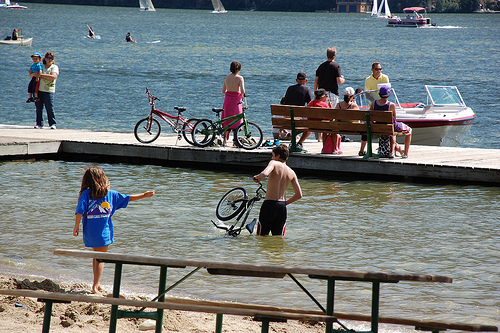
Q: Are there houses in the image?
A: No, there are no houses.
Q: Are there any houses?
A: No, there are no houses.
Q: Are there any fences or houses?
A: No, there are no houses or fences.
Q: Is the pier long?
A: Yes, the pier is long.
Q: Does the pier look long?
A: Yes, the pier is long.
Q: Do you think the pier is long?
A: Yes, the pier is long.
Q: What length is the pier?
A: The pier is long.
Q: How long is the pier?
A: The pier is long.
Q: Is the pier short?
A: No, the pier is long.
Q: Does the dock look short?
A: No, the dock is long.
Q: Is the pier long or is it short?
A: The pier is long.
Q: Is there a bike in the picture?
A: Yes, there is a bike.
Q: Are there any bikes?
A: Yes, there is a bike.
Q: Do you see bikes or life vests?
A: Yes, there is a bike.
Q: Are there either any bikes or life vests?
A: Yes, there is a bike.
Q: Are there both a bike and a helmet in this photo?
A: No, there is a bike but no helmets.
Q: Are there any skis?
A: No, there are no skis.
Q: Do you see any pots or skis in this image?
A: No, there are no skis or pots.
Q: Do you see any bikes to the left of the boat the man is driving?
A: Yes, there is a bike to the left of the boat.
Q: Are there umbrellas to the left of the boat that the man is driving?
A: No, there is a bike to the left of the boat.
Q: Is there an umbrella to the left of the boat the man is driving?
A: No, there is a bike to the left of the boat.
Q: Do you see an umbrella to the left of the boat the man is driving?
A: No, there is a bike to the left of the boat.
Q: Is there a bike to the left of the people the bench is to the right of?
A: Yes, there is a bike to the left of the people.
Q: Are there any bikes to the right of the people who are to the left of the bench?
A: No, the bike is to the left of the people.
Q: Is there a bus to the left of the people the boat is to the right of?
A: No, there is a bike to the left of the people.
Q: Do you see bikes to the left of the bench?
A: Yes, there is a bike to the left of the bench.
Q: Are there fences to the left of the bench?
A: No, there is a bike to the left of the bench.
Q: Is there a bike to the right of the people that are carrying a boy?
A: Yes, there is a bike to the right of the people.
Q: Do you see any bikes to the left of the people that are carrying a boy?
A: No, the bike is to the right of the people.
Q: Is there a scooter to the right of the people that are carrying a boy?
A: No, there is a bike to the right of the people.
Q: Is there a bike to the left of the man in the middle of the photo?
A: Yes, there is a bike to the left of the man.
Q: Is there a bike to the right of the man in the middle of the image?
A: No, the bike is to the left of the man.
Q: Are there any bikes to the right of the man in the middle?
A: No, the bike is to the left of the man.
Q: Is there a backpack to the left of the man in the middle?
A: No, there is a bike to the left of the man.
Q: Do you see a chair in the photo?
A: No, there are no chairs.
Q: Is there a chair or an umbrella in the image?
A: No, there are no chairs or umbrellas.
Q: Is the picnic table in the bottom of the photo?
A: Yes, the picnic table is in the bottom of the image.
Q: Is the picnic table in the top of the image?
A: No, the picnic table is in the bottom of the image.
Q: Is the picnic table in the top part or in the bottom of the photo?
A: The picnic table is in the bottom of the image.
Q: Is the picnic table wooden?
A: Yes, the picnic table is wooden.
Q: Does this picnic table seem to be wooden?
A: Yes, the picnic table is wooden.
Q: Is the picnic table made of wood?
A: Yes, the picnic table is made of wood.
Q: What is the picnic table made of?
A: The picnic table is made of wood.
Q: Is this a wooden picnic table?
A: Yes, this is a wooden picnic table.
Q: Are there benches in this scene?
A: Yes, there is a bench.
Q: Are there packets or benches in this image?
A: Yes, there is a bench.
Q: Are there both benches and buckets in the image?
A: No, there is a bench but no buckets.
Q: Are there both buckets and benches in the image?
A: No, there is a bench but no buckets.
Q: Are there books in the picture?
A: No, there are no books.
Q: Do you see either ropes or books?
A: No, there are no books or ropes.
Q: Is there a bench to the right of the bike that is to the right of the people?
A: Yes, there is a bench to the right of the bike.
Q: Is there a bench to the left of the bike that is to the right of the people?
A: No, the bench is to the right of the bike.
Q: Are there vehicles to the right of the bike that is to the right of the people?
A: No, there is a bench to the right of the bike.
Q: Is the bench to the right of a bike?
A: Yes, the bench is to the right of a bike.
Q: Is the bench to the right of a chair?
A: No, the bench is to the right of a bike.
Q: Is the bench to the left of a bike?
A: No, the bench is to the right of a bike.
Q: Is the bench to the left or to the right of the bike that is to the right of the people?
A: The bench is to the right of the bike.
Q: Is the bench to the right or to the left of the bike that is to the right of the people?
A: The bench is to the right of the bike.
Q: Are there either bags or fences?
A: No, there are no bags or fences.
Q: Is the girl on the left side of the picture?
A: Yes, the girl is on the left of the image.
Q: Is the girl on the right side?
A: No, the girl is on the left of the image.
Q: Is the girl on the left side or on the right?
A: The girl is on the left of the image.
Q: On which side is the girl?
A: The girl is on the left of the image.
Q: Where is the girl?
A: The girl is on the sand.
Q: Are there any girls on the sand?
A: Yes, there is a girl on the sand.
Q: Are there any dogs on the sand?
A: No, there is a girl on the sand.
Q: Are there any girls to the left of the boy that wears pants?
A: Yes, there is a girl to the left of the boy.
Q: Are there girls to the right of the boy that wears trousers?
A: No, the girl is to the left of the boy.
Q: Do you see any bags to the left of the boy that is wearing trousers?
A: No, there is a girl to the left of the boy.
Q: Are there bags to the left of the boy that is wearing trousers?
A: No, there is a girl to the left of the boy.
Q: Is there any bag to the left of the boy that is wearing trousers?
A: No, there is a girl to the left of the boy.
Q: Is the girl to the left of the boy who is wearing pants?
A: Yes, the girl is to the left of the boy.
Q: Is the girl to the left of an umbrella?
A: No, the girl is to the left of the boy.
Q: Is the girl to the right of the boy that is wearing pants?
A: No, the girl is to the left of the boy.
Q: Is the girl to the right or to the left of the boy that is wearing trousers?
A: The girl is to the left of the boy.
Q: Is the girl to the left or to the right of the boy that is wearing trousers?
A: The girl is to the left of the boy.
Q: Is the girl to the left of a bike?
A: Yes, the girl is to the left of a bike.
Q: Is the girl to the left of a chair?
A: No, the girl is to the left of a bike.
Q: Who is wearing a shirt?
A: The girl is wearing a shirt.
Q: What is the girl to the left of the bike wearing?
A: The girl is wearing a shirt.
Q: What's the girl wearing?
A: The girl is wearing a shirt.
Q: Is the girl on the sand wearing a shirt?
A: Yes, the girl is wearing a shirt.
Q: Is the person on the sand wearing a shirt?
A: Yes, the girl is wearing a shirt.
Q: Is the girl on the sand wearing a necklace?
A: No, the girl is wearing a shirt.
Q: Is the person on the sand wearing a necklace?
A: No, the girl is wearing a shirt.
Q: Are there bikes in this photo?
A: Yes, there is a bike.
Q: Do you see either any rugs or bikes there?
A: Yes, there is a bike.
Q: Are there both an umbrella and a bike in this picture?
A: No, there is a bike but no umbrellas.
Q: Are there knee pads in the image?
A: No, there are no knee pads.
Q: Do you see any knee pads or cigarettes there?
A: No, there are no knee pads or cigarettes.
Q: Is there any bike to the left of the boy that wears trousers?
A: Yes, there is a bike to the left of the boy.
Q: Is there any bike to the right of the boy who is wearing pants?
A: No, the bike is to the left of the boy.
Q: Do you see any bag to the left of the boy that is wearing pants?
A: No, there is a bike to the left of the boy.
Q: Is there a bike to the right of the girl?
A: Yes, there is a bike to the right of the girl.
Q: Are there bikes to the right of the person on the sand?
A: Yes, there is a bike to the right of the girl.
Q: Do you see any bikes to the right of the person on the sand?
A: Yes, there is a bike to the right of the girl.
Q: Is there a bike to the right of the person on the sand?
A: Yes, there is a bike to the right of the girl.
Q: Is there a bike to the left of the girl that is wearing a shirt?
A: No, the bike is to the right of the girl.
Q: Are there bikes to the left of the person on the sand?
A: No, the bike is to the right of the girl.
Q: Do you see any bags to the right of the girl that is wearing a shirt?
A: No, there is a bike to the right of the girl.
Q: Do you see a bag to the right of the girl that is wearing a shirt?
A: No, there is a bike to the right of the girl.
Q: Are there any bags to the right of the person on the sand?
A: No, there is a bike to the right of the girl.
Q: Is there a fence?
A: No, there are no fences.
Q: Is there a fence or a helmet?
A: No, there are no fences or helmets.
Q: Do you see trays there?
A: No, there are no trays.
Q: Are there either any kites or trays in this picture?
A: No, there are no trays or kites.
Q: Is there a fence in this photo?
A: No, there are no fences.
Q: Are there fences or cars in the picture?
A: No, there are no fences or cars.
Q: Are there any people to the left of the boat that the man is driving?
A: Yes, there are people to the left of the boat.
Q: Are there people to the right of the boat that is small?
A: No, the people are to the left of the boat.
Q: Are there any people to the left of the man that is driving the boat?
A: Yes, there are people to the left of the man.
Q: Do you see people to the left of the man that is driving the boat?
A: Yes, there are people to the left of the man.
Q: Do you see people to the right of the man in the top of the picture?
A: No, the people are to the left of the man.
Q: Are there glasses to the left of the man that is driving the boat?
A: No, there are people to the left of the man.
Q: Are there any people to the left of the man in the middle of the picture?
A: Yes, there are people to the left of the man.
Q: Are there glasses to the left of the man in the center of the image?
A: No, there are people to the left of the man.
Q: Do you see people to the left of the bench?
A: Yes, there are people to the left of the bench.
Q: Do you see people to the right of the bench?
A: No, the people are to the left of the bench.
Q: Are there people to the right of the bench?
A: No, the people are to the left of the bench.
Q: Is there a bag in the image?
A: No, there are no bags.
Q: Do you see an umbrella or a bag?
A: No, there are no bags or umbrellas.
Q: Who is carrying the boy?
A: The people are carrying the boy.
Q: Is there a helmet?
A: No, there are no helmets.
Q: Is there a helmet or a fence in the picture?
A: No, there are no helmets or fences.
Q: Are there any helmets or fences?
A: No, there are no helmets or fences.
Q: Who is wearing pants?
A: The boy is wearing pants.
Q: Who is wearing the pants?
A: The boy is wearing pants.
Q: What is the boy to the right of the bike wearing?
A: The boy is wearing trousers.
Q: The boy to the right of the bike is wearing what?
A: The boy is wearing trousers.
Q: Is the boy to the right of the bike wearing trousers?
A: Yes, the boy is wearing trousers.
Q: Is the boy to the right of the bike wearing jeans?
A: No, the boy is wearing trousers.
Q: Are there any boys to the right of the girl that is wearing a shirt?
A: Yes, there is a boy to the right of the girl.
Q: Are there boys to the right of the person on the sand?
A: Yes, there is a boy to the right of the girl.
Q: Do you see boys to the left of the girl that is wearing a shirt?
A: No, the boy is to the right of the girl.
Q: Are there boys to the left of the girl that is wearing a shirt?
A: No, the boy is to the right of the girl.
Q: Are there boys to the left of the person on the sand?
A: No, the boy is to the right of the girl.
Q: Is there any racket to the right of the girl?
A: No, there is a boy to the right of the girl.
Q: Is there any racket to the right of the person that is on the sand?
A: No, there is a boy to the right of the girl.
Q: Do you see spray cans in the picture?
A: No, there are no spray cans.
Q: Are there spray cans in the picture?
A: No, there are no spray cans.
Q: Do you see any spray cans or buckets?
A: No, there are no spray cans or buckets.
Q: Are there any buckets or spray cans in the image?
A: No, there are no spray cans or buckets.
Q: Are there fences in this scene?
A: No, there are no fences.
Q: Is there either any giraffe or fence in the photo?
A: No, there are no fences or giraffes.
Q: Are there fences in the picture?
A: No, there are no fences.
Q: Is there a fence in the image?
A: No, there are no fences.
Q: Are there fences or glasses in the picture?
A: No, there are no fences or glasses.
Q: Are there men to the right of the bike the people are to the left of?
A: Yes, there is a man to the right of the bike.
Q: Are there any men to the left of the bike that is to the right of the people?
A: No, the man is to the right of the bike.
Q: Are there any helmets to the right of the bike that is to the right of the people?
A: No, there is a man to the right of the bike.